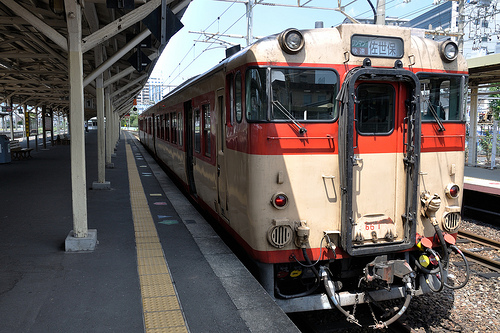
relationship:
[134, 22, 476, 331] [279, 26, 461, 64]
train has lights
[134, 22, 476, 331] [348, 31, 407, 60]
train has letters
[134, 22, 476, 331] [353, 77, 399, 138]
train has window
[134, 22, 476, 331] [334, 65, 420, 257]
train has door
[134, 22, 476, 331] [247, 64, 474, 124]
train has windshield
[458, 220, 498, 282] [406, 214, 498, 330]
tracks have rocks